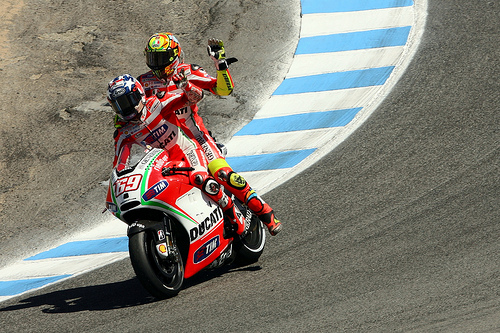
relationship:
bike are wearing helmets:
[104, 146, 267, 299] [96, 26, 178, 111]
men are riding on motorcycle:
[133, 33, 286, 236] [105, 158, 273, 289]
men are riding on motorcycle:
[103, 26, 218, 127] [106, 153, 263, 294]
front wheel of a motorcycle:
[126, 216, 185, 297] [171, 174, 252, 324]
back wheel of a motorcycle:
[248, 174, 269, 320] [187, 213, 227, 304]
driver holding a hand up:
[104, 73, 254, 242] [214, 99, 241, 107]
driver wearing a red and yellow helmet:
[104, 73, 254, 242] [127, 99, 192, 106]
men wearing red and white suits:
[133, 33, 286, 236] [153, 99, 208, 193]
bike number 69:
[104, 146, 267, 299] [112, 170, 139, 220]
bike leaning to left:
[104, 146, 267, 299] [91, 175, 160, 292]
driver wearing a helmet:
[112, 114, 170, 187] [101, 99, 146, 102]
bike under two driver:
[104, 146, 267, 299] [104, 73, 254, 242]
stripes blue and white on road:
[0, 9, 429, 300] [7, 232, 485, 333]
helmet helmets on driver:
[144, 30, 182, 78] [104, 73, 254, 242]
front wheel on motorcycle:
[132, 236, 172, 333] [99, 136, 274, 308]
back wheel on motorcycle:
[230, 190, 273, 263] [114, 156, 261, 333]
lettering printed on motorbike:
[188, 205, 223, 242] [98, 140, 268, 298]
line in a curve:
[268, 61, 397, 98] [182, 0, 442, 194]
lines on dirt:
[291, 23, 381, 136] [233, 19, 271, 52]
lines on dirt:
[299, 52, 392, 77] [46, 146, 75, 196]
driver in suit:
[104, 73, 254, 242] [120, 114, 209, 199]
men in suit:
[133, 33, 286, 236] [156, 77, 221, 132]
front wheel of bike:
[126, 216, 185, 297] [104, 146, 267, 299]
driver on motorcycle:
[104, 73, 254, 242] [115, 133, 272, 299]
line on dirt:
[0, 274, 81, 303] [2, 3, 304, 264]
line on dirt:
[24, 239, 134, 264] [2, 3, 304, 264]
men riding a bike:
[133, 33, 286, 236] [106, 133, 287, 308]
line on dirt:
[268, 61, 397, 98] [4, 3, 482, 322]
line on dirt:
[273, 60, 402, 91] [16, 2, 475, 279]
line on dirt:
[226, 147, 317, 171] [16, 2, 475, 279]